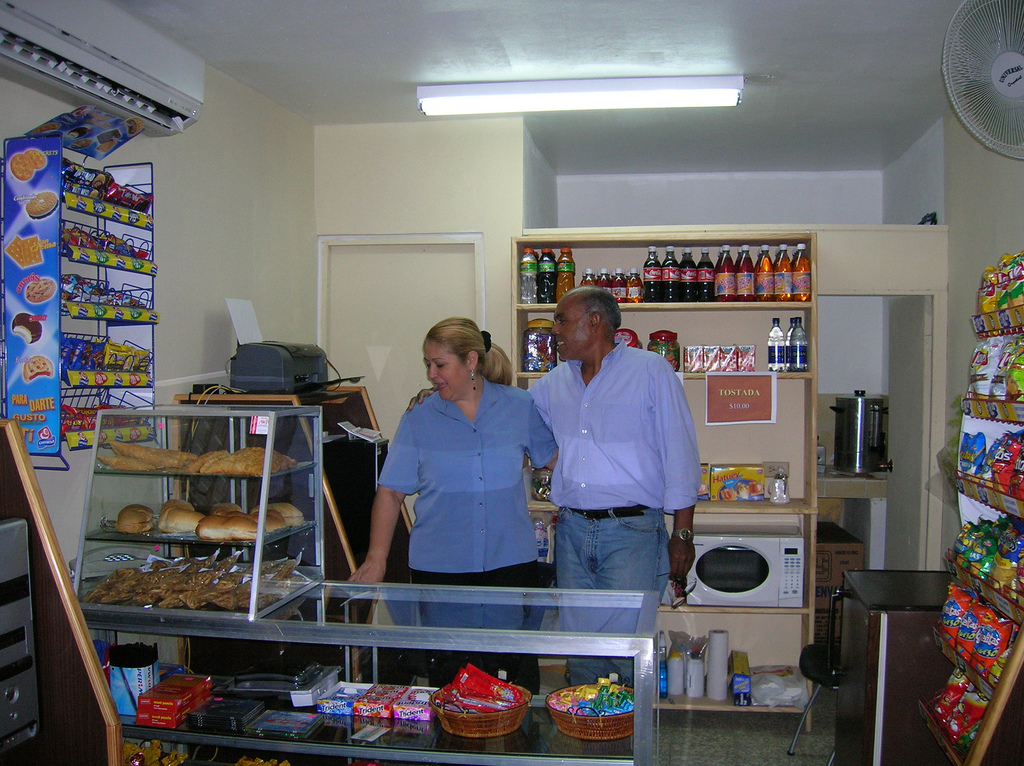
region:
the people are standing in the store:
[1, 2, 1017, 762]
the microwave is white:
[678, 527, 805, 608]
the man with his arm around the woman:
[346, 287, 701, 762]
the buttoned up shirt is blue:
[371, 380, 558, 577]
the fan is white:
[939, 0, 1022, 160]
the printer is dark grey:
[225, 328, 365, 395]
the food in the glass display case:
[73, 399, 321, 619]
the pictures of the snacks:
[5, 135, 63, 456]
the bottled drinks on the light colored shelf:
[509, 230, 816, 313]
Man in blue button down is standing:
[531, 287, 693, 585]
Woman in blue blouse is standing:
[368, 318, 558, 594]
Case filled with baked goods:
[64, 407, 322, 626]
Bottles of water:
[765, 315, 807, 369]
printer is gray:
[223, 294, 360, 389]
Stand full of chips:
[931, 247, 1021, 753]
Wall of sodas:
[640, 240, 811, 302]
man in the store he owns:
[526, 262, 726, 598]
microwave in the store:
[691, 524, 837, 613]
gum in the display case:
[320, 660, 435, 730]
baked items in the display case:
[61, 418, 278, 612]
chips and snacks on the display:
[936, 259, 1020, 732]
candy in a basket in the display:
[548, 672, 641, 733]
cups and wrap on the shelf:
[653, 616, 799, 706]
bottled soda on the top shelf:
[520, 244, 834, 298]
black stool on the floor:
[801, 631, 855, 749]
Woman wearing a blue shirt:
[378, 314, 569, 584]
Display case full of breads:
[66, 398, 327, 624]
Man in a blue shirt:
[527, 281, 704, 601]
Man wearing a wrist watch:
[536, 287, 710, 592]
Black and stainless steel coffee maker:
[827, 380, 910, 492]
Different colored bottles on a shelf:
[505, 231, 820, 320]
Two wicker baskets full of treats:
[426, 647, 641, 762]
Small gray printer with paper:
[187, 291, 378, 413]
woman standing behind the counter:
[367, 314, 551, 593]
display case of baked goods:
[81, 396, 319, 618]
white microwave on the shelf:
[676, 532, 806, 608]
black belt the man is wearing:
[562, 503, 651, 522]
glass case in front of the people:
[81, 557, 682, 755]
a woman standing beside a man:
[339, 315, 559, 762]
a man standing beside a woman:
[404, 282, 706, 761]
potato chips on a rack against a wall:
[913, 243, 1021, 762]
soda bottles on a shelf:
[512, 239, 819, 306]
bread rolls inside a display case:
[110, 494, 311, 548]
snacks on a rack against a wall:
[4, 129, 160, 471]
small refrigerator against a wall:
[822, 559, 1022, 762]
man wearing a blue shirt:
[523, 331, 702, 522]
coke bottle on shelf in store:
[636, 242, 663, 303]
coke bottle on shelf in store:
[658, 240, 684, 304]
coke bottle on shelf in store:
[696, 242, 719, 297]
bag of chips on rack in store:
[933, 578, 973, 651]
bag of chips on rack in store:
[989, 435, 1019, 493]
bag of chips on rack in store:
[953, 595, 992, 669]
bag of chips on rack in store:
[931, 656, 967, 730]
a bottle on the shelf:
[695, 250, 721, 308]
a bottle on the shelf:
[599, 234, 682, 343]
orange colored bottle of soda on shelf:
[787, 233, 813, 306]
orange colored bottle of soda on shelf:
[773, 239, 794, 303]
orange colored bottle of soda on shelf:
[752, 235, 779, 306]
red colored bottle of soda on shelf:
[714, 242, 737, 303]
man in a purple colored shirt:
[520, 282, 707, 684]